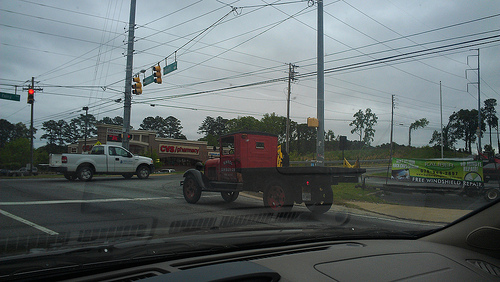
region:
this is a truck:
[178, 121, 351, 203]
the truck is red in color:
[224, 133, 274, 160]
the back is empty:
[266, 143, 353, 180]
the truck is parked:
[107, 156, 123, 171]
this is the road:
[39, 185, 84, 220]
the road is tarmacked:
[43, 181, 104, 216]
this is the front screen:
[295, 44, 455, 221]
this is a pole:
[307, 10, 335, 62]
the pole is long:
[308, 40, 337, 106]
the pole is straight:
[311, 65, 336, 122]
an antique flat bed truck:
[180, 127, 366, 216]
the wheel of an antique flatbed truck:
[176, 169, 204, 206]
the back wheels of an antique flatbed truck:
[257, 187, 299, 218]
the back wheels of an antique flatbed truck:
[310, 179, 335, 214]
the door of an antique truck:
[215, 136, 237, 186]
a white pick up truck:
[50, 138, 156, 181]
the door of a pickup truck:
[111, 143, 131, 175]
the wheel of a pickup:
[134, 160, 152, 182]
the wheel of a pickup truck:
[74, 159, 99, 184]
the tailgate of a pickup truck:
[34, 158, 66, 173]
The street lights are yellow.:
[111, 57, 168, 87]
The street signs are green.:
[137, 62, 183, 85]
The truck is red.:
[172, 128, 353, 217]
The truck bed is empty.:
[243, 135, 360, 181]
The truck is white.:
[43, 138, 150, 181]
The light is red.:
[21, 70, 33, 105]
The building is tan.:
[63, 130, 210, 167]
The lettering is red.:
[153, 140, 204, 156]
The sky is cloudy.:
[3, 5, 486, 133]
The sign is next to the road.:
[380, 150, 492, 194]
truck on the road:
[47, 139, 156, 186]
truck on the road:
[173, 130, 378, 220]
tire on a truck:
[72, 160, 97, 182]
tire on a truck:
[134, 161, 153, 181]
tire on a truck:
[175, 168, 205, 204]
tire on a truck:
[217, 188, 242, 202]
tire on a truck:
[252, 174, 304, 217]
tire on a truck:
[300, 179, 338, 213]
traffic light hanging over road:
[147, 59, 164, 90]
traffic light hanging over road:
[126, 68, 147, 100]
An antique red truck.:
[175, 120, 365, 215]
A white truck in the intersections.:
[41, 132, 161, 185]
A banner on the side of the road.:
[380, 145, 490, 207]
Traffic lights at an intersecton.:
[12, 65, 180, 107]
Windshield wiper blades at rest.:
[2, 213, 359, 271]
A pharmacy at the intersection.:
[72, 123, 215, 180]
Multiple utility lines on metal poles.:
[82, 11, 497, 101]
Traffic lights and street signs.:
[128, 48, 190, 97]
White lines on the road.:
[5, 180, 183, 228]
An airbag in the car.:
[315, 242, 491, 280]